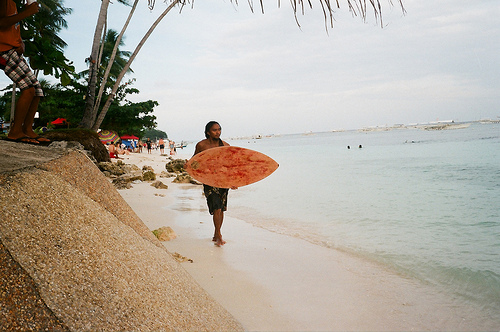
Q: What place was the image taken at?
A: It was taken at the beach.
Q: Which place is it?
A: It is a beach.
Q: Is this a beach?
A: Yes, it is a beach.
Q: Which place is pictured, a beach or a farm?
A: It is a beach.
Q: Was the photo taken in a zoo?
A: No, the picture was taken in a beach.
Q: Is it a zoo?
A: No, it is a beach.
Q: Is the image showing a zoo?
A: No, the picture is showing a beach.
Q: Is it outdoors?
A: Yes, it is outdoors.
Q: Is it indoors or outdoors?
A: It is outdoors.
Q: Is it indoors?
A: No, it is outdoors.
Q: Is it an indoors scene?
A: No, it is outdoors.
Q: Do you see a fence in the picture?
A: No, there are no fences.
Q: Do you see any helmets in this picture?
A: No, there are no helmets.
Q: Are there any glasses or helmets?
A: No, there are no helmets or glasses.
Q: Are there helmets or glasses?
A: No, there are no helmets or glasses.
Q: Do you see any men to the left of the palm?
A: Yes, there is a man to the left of the palm.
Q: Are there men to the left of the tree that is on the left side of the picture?
A: Yes, there is a man to the left of the palm.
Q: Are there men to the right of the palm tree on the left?
A: No, the man is to the left of the palm.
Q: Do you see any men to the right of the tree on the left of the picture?
A: No, the man is to the left of the palm.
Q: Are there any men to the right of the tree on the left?
A: No, the man is to the left of the palm.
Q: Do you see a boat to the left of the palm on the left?
A: No, there is a man to the left of the palm.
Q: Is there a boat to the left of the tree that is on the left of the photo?
A: No, there is a man to the left of the palm.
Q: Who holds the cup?
A: The man holds the cup.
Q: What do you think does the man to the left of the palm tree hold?
A: The man holds the cup.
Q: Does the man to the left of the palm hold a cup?
A: Yes, the man holds a cup.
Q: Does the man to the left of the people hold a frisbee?
A: No, the man holds a cup.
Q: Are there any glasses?
A: No, there are no glasses.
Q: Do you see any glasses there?
A: No, there are no glasses.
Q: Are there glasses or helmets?
A: No, there are no glasses or helmets.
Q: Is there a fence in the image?
A: No, there are no fences.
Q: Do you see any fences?
A: No, there are no fences.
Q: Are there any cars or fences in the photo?
A: No, there are no fences or cars.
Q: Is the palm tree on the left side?
A: Yes, the palm tree is on the left of the image.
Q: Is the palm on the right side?
A: No, the palm is on the left of the image.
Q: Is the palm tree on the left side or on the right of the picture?
A: The palm tree is on the left of the image.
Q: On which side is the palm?
A: The palm is on the left of the image.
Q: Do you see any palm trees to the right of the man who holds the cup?
A: Yes, there is a palm tree to the right of the man.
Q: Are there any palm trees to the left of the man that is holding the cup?
A: No, the palm tree is to the right of the man.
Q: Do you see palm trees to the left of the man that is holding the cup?
A: No, the palm tree is to the right of the man.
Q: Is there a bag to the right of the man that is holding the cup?
A: No, there is a palm tree to the right of the man.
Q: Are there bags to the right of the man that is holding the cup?
A: No, there is a palm tree to the right of the man.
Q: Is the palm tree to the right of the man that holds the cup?
A: Yes, the palm tree is to the right of the man.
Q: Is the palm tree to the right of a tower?
A: No, the palm tree is to the right of the man.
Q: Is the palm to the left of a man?
A: No, the palm is to the right of a man.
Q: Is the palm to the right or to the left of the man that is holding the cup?
A: The palm is to the right of the man.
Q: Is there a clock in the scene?
A: No, there are no clocks.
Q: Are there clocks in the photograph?
A: No, there are no clocks.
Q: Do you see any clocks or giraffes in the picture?
A: No, there are no clocks or giraffes.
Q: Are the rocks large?
A: Yes, the rocks are large.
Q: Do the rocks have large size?
A: Yes, the rocks are large.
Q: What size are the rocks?
A: The rocks are large.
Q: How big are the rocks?
A: The rocks are large.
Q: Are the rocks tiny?
A: No, the rocks are large.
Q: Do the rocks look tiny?
A: No, the rocks are large.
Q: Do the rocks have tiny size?
A: No, the rocks are large.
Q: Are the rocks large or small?
A: The rocks are large.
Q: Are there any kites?
A: No, there are no kites.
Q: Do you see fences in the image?
A: No, there are no fences.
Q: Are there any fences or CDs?
A: No, there are no fences or cds.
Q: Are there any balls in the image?
A: No, there are no balls.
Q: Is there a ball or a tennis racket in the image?
A: No, there are no balls or rackets.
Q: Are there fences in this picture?
A: No, there are no fences.